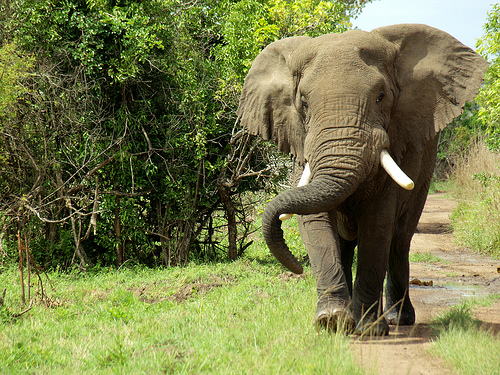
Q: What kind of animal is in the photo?
A: Elephant.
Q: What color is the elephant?
A: Grayish.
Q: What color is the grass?
A: Green.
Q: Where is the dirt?
A: On the trail.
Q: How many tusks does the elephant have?
A: 2.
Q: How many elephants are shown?
A: 1.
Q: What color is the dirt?
A: Brown.